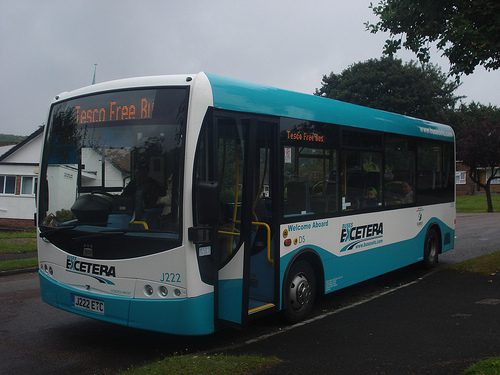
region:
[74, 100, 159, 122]
the words Jesco Free Bus on the front of a bus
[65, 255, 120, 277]
the word Excetera on the front of a bus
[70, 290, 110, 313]
the plate J222 ETC on the front of a bus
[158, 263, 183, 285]
J222 in blue on the front of a bus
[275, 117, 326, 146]
Tesco Free Bus on the side of the bus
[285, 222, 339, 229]
Welcome Aboard on the side of a bus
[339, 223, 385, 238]
Excetera on the side of the bus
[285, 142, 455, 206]
passenger windows on the side of the bus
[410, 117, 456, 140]
a website on the side of the bus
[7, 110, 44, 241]
a white house behind a bus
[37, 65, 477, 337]
Light blue and white bus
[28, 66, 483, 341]
Blue and white bus with orange digital sign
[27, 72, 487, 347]
Blue and white bus with Excetera sign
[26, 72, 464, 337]
Blue and white bus number J222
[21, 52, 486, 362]
Blue and white bus on roadway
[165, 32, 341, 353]
open bus door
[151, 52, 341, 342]
open bus door with yellow hand rails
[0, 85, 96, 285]
white and brick house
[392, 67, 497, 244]
brick house with white windows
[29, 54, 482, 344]
Blue and white charter bus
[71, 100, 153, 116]
Marquee display on the front of the bus.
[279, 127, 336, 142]
Marquee display on the side of the bus.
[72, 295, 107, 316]
License plate on the front of the bus.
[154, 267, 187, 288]
Letter J and number on the front of the bus.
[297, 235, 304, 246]
Letter D and 5 on the side of the bus.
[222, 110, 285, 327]
Opened doors on the side of the bus.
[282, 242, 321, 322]
Front tire on the side of the bus.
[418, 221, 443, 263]
Back tire on the side of the bus.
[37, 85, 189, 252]
Front windshield window on the front of the bus.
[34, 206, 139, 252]
Windshield wipers on the front of the bus.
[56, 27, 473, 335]
free bus rides on quiet suburban steet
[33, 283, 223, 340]
bottom of front bumper is blue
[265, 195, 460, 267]
white stripe is in middle of bus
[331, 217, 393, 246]
black letters on the bus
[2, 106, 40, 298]
small white house in background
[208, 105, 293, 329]
entrance to bus is open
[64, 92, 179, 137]
tesco free bus on top front of bus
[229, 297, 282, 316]
yellow step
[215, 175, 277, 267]
yellow hand railings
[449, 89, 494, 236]
tree and house in background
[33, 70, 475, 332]
Blue and white bus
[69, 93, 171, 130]
Sign that reads Tesco Free Bus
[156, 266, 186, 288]
J222 on the front of the bus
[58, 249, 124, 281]
Excetera written on front of bus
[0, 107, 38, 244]
House to the left of the bus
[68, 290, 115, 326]
License plate that reads J222 ETC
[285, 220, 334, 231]
Welcome Aboard written on side of bus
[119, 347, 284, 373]
Patch of green grass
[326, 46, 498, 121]
Tops of trees in the background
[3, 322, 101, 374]
Portion of the street the bus is traveling on